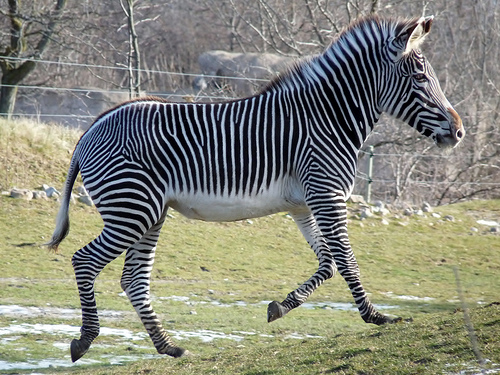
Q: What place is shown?
A: It is a park.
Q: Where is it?
A: This is at the park.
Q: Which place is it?
A: It is a park.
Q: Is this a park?
A: Yes, it is a park.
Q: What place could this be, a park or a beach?
A: It is a park.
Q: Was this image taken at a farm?
A: No, the picture was taken in a park.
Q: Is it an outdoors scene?
A: Yes, it is outdoors.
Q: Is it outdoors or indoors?
A: It is outdoors.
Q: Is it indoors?
A: No, it is outdoors.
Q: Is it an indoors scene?
A: No, it is outdoors.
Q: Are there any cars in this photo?
A: No, there are no cars.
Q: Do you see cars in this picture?
A: No, there are no cars.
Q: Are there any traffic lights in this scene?
A: No, there are no traffic lights.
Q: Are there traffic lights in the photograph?
A: No, there are no traffic lights.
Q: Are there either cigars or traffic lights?
A: No, there are no traffic lights or cigars.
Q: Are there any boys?
A: No, there are no boys.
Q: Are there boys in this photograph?
A: No, there are no boys.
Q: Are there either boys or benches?
A: No, there are no boys or benches.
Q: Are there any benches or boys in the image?
A: No, there are no boys or benches.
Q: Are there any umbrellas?
A: No, there are no umbrellas.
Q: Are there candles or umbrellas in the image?
A: No, there are no umbrellas or candles.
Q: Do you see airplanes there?
A: No, there are no airplanes.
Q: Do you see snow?
A: Yes, there is snow.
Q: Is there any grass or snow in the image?
A: Yes, there is snow.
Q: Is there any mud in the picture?
A: No, there is no mud.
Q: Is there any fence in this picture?
A: Yes, there is a fence.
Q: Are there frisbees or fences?
A: Yes, there is a fence.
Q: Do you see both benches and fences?
A: No, there is a fence but no benches.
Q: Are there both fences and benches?
A: No, there is a fence but no benches.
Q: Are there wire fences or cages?
A: Yes, there is a wire fence.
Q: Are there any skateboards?
A: No, there are no skateboards.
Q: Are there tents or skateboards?
A: No, there are no skateboards or tents.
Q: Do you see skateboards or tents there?
A: No, there are no skateboards or tents.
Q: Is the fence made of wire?
A: Yes, the fence is made of wire.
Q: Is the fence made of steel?
A: No, the fence is made of wire.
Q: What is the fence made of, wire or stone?
A: The fence is made of wire.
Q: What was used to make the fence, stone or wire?
A: The fence is made of wire.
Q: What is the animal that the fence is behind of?
A: The animal is a zebra.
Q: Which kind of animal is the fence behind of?
A: The fence is behind the zebra.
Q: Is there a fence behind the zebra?
A: Yes, there is a fence behind the zebra.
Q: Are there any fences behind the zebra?
A: Yes, there is a fence behind the zebra.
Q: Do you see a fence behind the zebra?
A: Yes, there is a fence behind the zebra.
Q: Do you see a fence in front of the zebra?
A: No, the fence is behind the zebra.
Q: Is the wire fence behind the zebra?
A: Yes, the fence is behind the zebra.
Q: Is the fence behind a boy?
A: No, the fence is behind the zebra.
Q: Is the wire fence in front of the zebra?
A: No, the fence is behind the zebra.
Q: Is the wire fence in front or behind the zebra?
A: The fence is behind the zebra.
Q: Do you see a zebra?
A: Yes, there is a zebra.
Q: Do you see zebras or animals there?
A: Yes, there is a zebra.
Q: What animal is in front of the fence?
A: The zebra is in front of the fence.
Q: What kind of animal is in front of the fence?
A: The animal is a zebra.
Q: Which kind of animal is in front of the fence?
A: The animal is a zebra.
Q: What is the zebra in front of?
A: The zebra is in front of the fence.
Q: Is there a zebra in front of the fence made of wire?
A: Yes, there is a zebra in front of the fence.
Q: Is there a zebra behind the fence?
A: No, the zebra is in front of the fence.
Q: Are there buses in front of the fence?
A: No, there is a zebra in front of the fence.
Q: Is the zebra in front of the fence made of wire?
A: Yes, the zebra is in front of the fence.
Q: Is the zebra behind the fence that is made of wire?
A: No, the zebra is in front of the fence.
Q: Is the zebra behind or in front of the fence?
A: The zebra is in front of the fence.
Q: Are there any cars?
A: No, there are no cars.